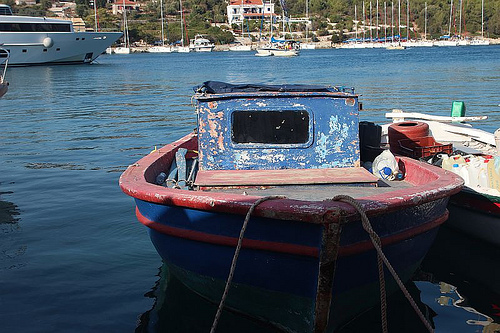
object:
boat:
[119, 82, 465, 331]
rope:
[379, 243, 385, 332]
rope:
[210, 195, 288, 332]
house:
[226, 1, 274, 38]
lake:
[147, 53, 498, 82]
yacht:
[0, 4, 124, 66]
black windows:
[51, 23, 71, 31]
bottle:
[156, 172, 166, 184]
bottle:
[452, 163, 469, 186]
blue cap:
[453, 163, 458, 168]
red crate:
[399, 136, 453, 156]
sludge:
[438, 281, 456, 294]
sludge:
[437, 295, 454, 305]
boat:
[189, 34, 214, 53]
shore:
[215, 42, 342, 49]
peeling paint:
[199, 103, 230, 167]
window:
[233, 112, 308, 144]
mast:
[180, 0, 184, 47]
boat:
[175, 46, 191, 53]